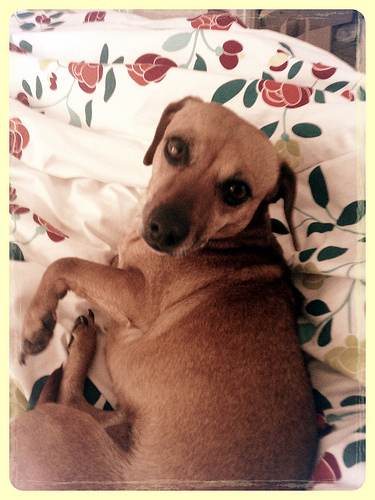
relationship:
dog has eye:
[8, 93, 317, 496] [162, 131, 194, 168]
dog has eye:
[8, 93, 317, 496] [215, 172, 256, 208]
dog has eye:
[8, 93, 317, 496] [215, 175, 257, 213]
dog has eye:
[8, 93, 317, 496] [158, 132, 194, 171]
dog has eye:
[8, 93, 317, 496] [217, 178, 255, 209]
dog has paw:
[8, 93, 317, 496] [16, 288, 62, 366]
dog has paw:
[8, 93, 317, 496] [60, 301, 105, 381]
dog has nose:
[8, 93, 317, 496] [144, 205, 189, 250]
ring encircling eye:
[218, 168, 252, 213] [217, 169, 253, 205]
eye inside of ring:
[217, 169, 253, 205] [218, 168, 252, 213]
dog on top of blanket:
[8, 93, 317, 496] [25, 23, 345, 93]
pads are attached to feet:
[20, 313, 57, 360] [16, 281, 108, 362]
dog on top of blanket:
[38, 93, 316, 485] [25, 23, 345, 93]